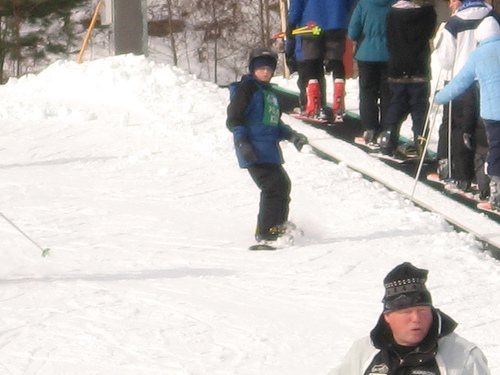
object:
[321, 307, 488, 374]
jacket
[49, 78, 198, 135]
snow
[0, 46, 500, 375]
hill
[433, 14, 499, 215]
boy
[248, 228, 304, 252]
snowboard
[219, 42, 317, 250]
boy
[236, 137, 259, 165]
gloves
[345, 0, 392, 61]
jacket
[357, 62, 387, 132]
pants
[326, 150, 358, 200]
ground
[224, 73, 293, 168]
jacket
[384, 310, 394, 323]
ear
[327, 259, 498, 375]
man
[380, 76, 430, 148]
pants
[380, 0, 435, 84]
hoody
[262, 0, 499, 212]
people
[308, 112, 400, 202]
line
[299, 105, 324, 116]
foot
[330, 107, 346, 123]
foot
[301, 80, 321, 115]
boot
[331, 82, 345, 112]
boot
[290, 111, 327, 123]
ski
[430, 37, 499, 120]
jacket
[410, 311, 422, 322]
nose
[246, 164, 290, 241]
pants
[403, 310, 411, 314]
eye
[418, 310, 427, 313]
eye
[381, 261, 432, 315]
hat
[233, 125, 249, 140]
sleeves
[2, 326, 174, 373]
snow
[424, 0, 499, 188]
person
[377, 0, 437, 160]
person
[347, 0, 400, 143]
person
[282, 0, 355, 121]
person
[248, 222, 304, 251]
skate